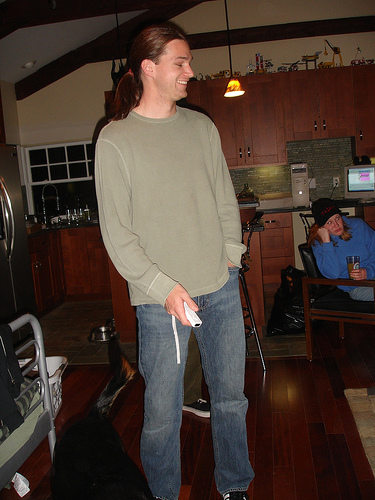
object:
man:
[93, 20, 253, 500]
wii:
[179, 296, 203, 330]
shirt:
[93, 107, 249, 309]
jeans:
[136, 266, 252, 498]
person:
[310, 197, 374, 306]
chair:
[297, 233, 375, 359]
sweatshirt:
[314, 216, 374, 289]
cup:
[346, 254, 362, 280]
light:
[222, 79, 247, 97]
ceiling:
[0, 1, 375, 105]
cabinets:
[180, 69, 374, 166]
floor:
[0, 361, 375, 500]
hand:
[163, 281, 199, 329]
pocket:
[224, 263, 241, 294]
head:
[313, 200, 344, 235]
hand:
[317, 228, 331, 242]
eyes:
[174, 59, 185, 70]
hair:
[101, 22, 186, 124]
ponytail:
[91, 60, 138, 124]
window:
[18, 143, 96, 217]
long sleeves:
[91, 142, 175, 306]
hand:
[349, 269, 365, 281]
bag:
[266, 263, 314, 335]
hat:
[311, 198, 343, 229]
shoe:
[179, 396, 213, 416]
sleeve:
[313, 241, 343, 285]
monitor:
[341, 163, 374, 203]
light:
[19, 59, 38, 71]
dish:
[89, 322, 113, 342]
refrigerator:
[2, 105, 37, 356]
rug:
[247, 334, 310, 359]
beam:
[189, 18, 375, 49]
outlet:
[332, 176, 340, 189]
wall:
[223, 134, 373, 207]